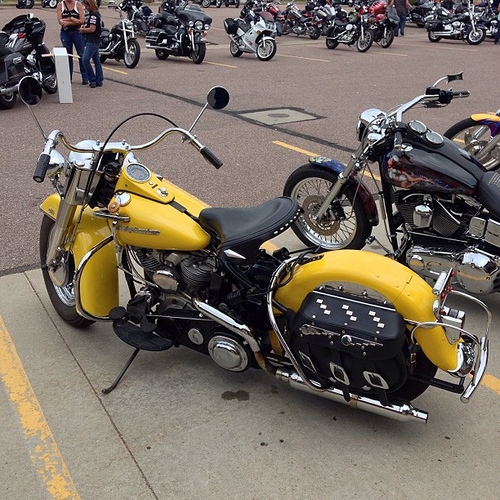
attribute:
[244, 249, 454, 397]
bag — leather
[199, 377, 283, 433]
spot — oil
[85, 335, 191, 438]
stand — black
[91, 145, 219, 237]
tank — yellow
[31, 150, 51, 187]
grip — black, handle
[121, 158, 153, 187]
gauge — speed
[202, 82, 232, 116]
mirror — round, side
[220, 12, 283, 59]
bike — white, street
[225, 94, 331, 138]
cement — square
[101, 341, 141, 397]
stand — black, metal, kick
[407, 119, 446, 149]
gauges — gas, speed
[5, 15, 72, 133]
motorcycle — displayed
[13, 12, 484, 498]
lot — parking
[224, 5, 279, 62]
motorcycle — white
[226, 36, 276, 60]
tires — black, rubber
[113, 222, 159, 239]
logo — chrome, painted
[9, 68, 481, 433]
bike — yellow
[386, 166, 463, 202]
design — airbrushed, painted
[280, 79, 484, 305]
motorcycle — black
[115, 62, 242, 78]
lines — yellow, painted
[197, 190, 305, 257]
seat — black , leather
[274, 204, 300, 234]
studs — silver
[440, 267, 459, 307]
lights — red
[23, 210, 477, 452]
space — parking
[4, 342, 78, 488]
line — yellow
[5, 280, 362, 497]
space — parking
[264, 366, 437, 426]
tailpipe — metal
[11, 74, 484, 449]
motorcycle — yellow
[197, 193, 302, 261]
seat — leather, black, motorcycle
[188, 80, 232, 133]
mirror — rear view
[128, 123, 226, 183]
handlebar — motorcycle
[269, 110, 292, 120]
top — metal, lot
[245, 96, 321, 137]
surface — parking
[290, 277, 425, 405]
case — black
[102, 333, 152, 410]
stand — kick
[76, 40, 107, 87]
jeans — pair, blue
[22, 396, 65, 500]
strip — yellow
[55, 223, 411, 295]
motorbike — yellow and black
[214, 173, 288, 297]
seat —  black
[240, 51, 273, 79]
motorbike — white and black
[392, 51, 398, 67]
motorbike — red and black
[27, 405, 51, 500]
mark — yellow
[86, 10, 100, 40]
t-shirt — black